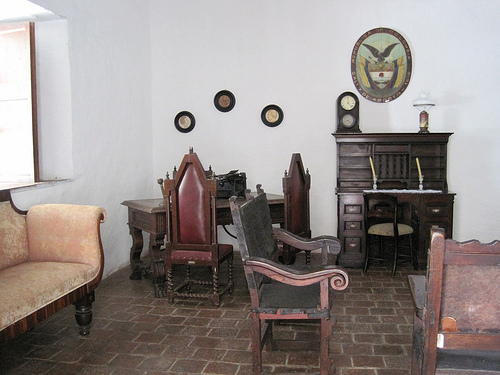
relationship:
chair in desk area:
[228, 184, 350, 374] [118, 142, 266, 270]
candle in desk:
[369, 156, 378, 190] [333, 130, 454, 272]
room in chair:
[47, 7, 480, 329] [167, 160, 239, 322]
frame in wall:
[350, 26, 413, 104] [149, 5, 490, 246]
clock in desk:
[334, 91, 362, 133] [333, 130, 454, 272]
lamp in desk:
[411, 90, 436, 135] [333, 130, 454, 272]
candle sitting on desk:
[369, 156, 378, 190] [309, 115, 489, 272]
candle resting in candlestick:
[369, 156, 378, 190] [364, 149, 376, 189]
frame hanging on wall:
[350, 26, 413, 104] [149, 5, 490, 246]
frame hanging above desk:
[350, 26, 413, 104] [333, 130, 454, 272]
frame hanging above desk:
[351, 25, 414, 109] [333, 130, 454, 272]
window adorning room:
[3, 0, 72, 197] [2, 1, 484, 372]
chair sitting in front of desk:
[358, 187, 424, 277] [333, 130, 454, 272]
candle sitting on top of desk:
[363, 154, 378, 190] [333, 130, 454, 272]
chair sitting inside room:
[217, 193, 348, 371] [2, 1, 484, 372]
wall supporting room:
[86, 21, 246, 103] [12, 21, 493, 349]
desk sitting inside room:
[333, 130, 454, 272] [2, 1, 484, 372]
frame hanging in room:
[350, 26, 413, 104] [2, 1, 484, 372]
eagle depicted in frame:
[361, 40, 399, 64] [350, 26, 413, 104]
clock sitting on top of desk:
[334, 91, 362, 133] [332, 124, 459, 213]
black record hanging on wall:
[252, 97, 302, 144] [126, 15, 499, 171]